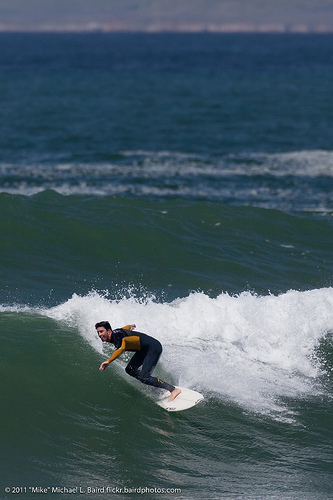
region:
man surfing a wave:
[76, 312, 233, 430]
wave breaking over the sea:
[189, 295, 308, 407]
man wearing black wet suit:
[87, 312, 189, 415]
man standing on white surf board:
[117, 373, 250, 426]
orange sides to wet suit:
[111, 335, 143, 386]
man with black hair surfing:
[93, 316, 207, 434]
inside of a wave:
[16, 334, 105, 433]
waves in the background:
[83, 150, 291, 199]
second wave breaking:
[44, 194, 254, 300]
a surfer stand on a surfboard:
[81, 302, 185, 409]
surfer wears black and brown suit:
[70, 311, 185, 408]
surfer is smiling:
[88, 313, 186, 406]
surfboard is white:
[112, 361, 209, 416]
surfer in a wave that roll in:
[5, 280, 331, 415]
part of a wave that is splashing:
[160, 284, 331, 342]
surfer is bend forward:
[84, 313, 184, 403]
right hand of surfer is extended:
[117, 318, 142, 332]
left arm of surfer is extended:
[94, 341, 127, 376]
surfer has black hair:
[81, 313, 134, 360]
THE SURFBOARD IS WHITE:
[174, 405, 180, 411]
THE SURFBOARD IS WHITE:
[174, 398, 179, 405]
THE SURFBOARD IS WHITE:
[172, 403, 185, 412]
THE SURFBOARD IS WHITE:
[175, 393, 186, 411]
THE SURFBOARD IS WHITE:
[180, 393, 192, 410]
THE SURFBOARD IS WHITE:
[181, 401, 189, 412]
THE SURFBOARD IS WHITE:
[182, 396, 189, 405]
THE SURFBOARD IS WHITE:
[178, 404, 187, 415]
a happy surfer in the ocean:
[85, 311, 186, 406]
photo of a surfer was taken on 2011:
[0, 296, 244, 496]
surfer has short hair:
[83, 308, 131, 359]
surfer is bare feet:
[82, 309, 186, 412]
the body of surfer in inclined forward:
[86, 312, 184, 407]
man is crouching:
[88, 312, 184, 407]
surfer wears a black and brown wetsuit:
[89, 310, 207, 417]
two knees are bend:
[118, 356, 161, 389]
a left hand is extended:
[92, 338, 131, 374]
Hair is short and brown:
[91, 320, 113, 330]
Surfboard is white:
[139, 377, 208, 412]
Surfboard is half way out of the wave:
[152, 385, 207, 414]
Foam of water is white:
[47, 286, 332, 353]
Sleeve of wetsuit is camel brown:
[104, 339, 128, 363]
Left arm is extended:
[93, 337, 124, 378]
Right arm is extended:
[117, 322, 137, 332]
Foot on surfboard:
[166, 385, 180, 402]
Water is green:
[0, 173, 331, 498]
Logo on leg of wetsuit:
[156, 376, 165, 387]